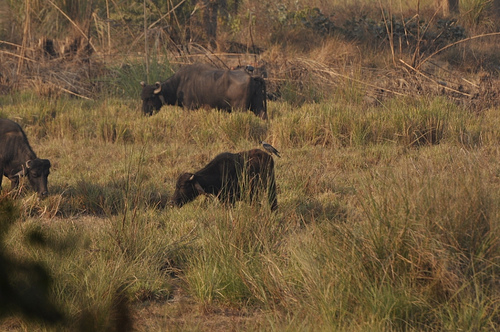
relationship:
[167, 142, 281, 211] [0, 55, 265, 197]
adult steer on family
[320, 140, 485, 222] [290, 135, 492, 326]
patch on grass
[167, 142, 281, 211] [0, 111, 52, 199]
adult steer staying close adult steer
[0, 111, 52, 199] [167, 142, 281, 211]
adult steer staying close adult steer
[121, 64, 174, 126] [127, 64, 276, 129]
head on cow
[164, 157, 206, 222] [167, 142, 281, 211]
head on adult steer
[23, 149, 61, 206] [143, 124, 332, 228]
head on cow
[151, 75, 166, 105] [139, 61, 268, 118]
horn on adult steer